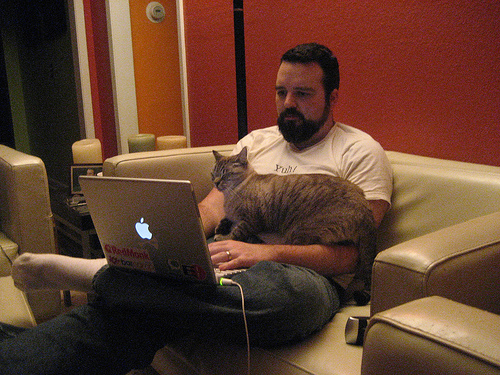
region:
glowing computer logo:
[133, 215, 155, 242]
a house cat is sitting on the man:
[206, 150, 373, 275]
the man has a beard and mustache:
[265, 89, 333, 140]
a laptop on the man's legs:
[79, 173, 249, 283]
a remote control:
[343, 313, 370, 347]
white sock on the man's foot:
[12, 251, 114, 292]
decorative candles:
[72, 133, 190, 159]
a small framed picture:
[67, 164, 103, 193]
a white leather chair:
[100, 143, 492, 344]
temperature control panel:
[144, 1, 166, 23]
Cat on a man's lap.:
[212, 143, 379, 283]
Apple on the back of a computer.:
[127, 212, 162, 242]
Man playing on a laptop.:
[50, 7, 400, 357]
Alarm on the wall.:
[145, 0, 166, 24]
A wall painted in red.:
[365, 34, 485, 138]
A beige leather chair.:
[350, 148, 497, 321]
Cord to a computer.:
[218, 271, 264, 373]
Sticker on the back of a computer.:
[100, 235, 159, 277]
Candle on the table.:
[61, 125, 111, 162]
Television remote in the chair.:
[345, 311, 374, 350]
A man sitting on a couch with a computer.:
[0, 40, 495, 372]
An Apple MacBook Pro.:
[76, 173, 234, 286]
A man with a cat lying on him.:
[2, 42, 391, 371]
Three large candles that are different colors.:
[71, 135, 186, 162]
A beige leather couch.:
[101, 143, 498, 374]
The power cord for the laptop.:
[217, 275, 252, 373]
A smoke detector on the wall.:
[146, 2, 166, 24]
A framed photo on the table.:
[67, 161, 104, 196]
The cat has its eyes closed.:
[210, 144, 377, 306]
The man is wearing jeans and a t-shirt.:
[5, 43, 391, 374]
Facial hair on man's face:
[273, 96, 334, 147]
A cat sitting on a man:
[206, 34, 397, 309]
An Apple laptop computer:
[73, 165, 258, 294]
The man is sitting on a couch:
[2, 38, 498, 372]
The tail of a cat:
[347, 228, 380, 309]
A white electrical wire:
[216, 272, 256, 373]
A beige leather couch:
[96, 140, 496, 370]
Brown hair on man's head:
[276, 36, 346, 92]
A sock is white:
[9, 249, 109, 297]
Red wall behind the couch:
[182, 1, 498, 168]